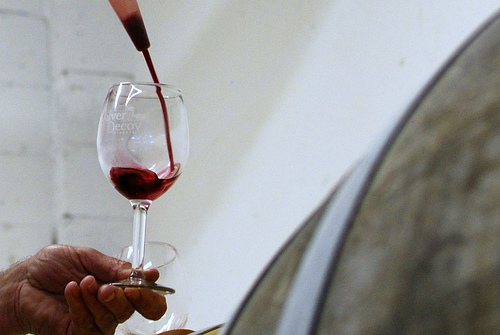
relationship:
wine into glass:
[110, 10, 191, 173] [99, 75, 185, 207]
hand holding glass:
[10, 223, 180, 332] [99, 75, 185, 207]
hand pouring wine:
[10, 223, 180, 332] [110, 10, 191, 173]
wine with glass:
[110, 10, 191, 173] [99, 75, 185, 207]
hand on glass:
[10, 223, 180, 332] [99, 75, 185, 207]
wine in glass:
[110, 10, 191, 173] [99, 75, 185, 207]